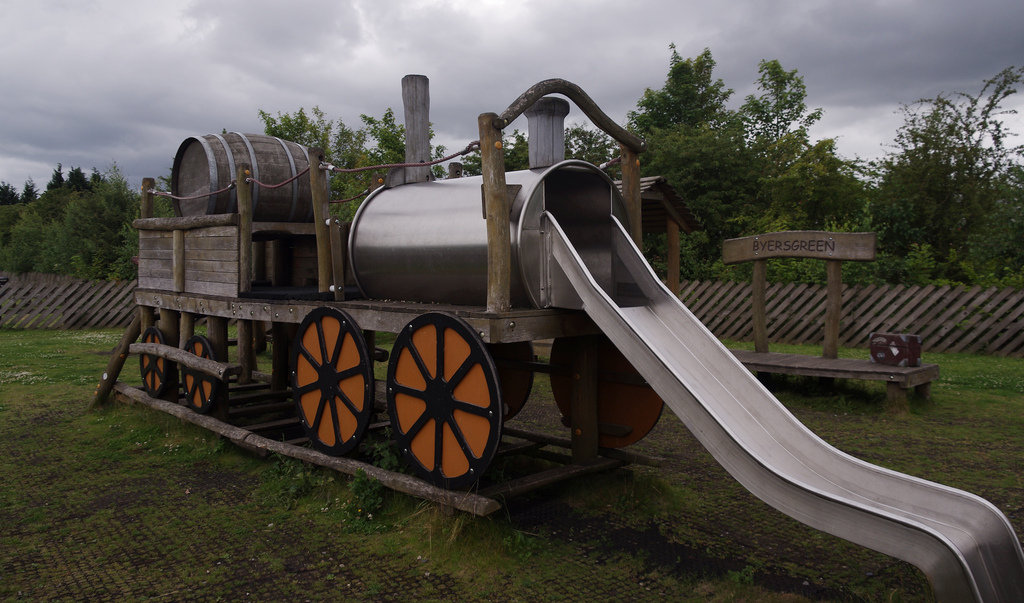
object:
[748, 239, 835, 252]
letters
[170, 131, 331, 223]
barrel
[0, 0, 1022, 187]
sky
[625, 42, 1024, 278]
trees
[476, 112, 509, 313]
pole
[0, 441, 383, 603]
grass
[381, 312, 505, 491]
wheel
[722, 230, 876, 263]
sign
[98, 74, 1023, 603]
playground equipment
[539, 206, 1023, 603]
slide